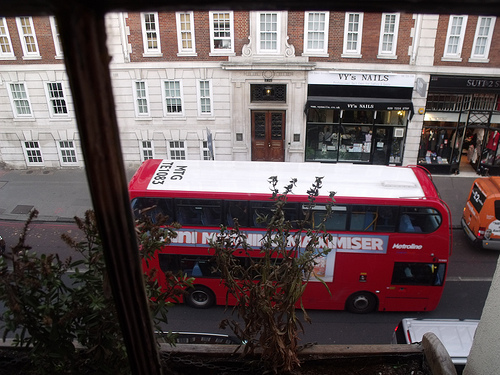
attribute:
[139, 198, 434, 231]
windows — closed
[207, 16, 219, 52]
pane — white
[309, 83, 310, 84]
roof — white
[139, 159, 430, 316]
bus — red, white, double decker, parked, two-story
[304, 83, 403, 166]
store front — black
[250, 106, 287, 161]
door — closed, brown, wooden, double, dark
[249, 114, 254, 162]
frame — wood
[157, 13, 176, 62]
wall — red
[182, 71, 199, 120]
wall — white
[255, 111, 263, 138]
windows — glass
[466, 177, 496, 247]
automobile — orange, white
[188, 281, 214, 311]
tire — rubber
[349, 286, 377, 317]
tire — rubber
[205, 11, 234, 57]
window — glass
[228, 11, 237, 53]
trim — white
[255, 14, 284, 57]
window — glass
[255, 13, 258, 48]
trim — white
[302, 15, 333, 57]
window — glass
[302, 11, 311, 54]
trim — white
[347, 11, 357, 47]
window — glass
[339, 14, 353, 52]
trim — white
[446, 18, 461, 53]
window — glass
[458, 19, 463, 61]
trim — white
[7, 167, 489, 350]
street — photographed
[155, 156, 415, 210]
roof — white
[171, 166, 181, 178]
letters — printed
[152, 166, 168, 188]
numbers — printed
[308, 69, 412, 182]
salon — vy's nails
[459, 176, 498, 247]
vehicle — orange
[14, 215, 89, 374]
plants — dry-looking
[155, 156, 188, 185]
text — black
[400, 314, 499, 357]
vehicle — white, silver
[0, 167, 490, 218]
sidewalk — grey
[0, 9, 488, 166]
building — white, brick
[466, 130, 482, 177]
entrance — open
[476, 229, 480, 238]
light — illuminated, red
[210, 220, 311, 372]
plant — dying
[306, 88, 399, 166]
shop — black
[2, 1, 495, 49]
windows — white